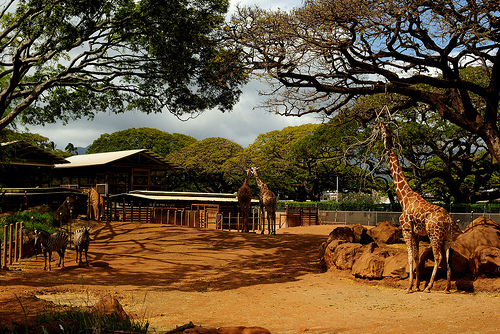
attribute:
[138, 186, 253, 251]
fence — wooden